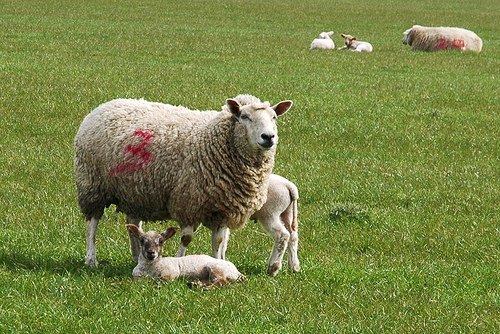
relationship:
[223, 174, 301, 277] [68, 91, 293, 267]
animal next to sheep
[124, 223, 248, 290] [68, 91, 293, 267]
baby next to sheep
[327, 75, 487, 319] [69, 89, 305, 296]
clean grass for sheep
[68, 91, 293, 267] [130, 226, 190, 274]
sheep with baby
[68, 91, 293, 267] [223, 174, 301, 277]
sheep with animal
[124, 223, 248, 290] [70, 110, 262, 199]
baby near sheep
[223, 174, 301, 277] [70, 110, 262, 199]
animal near sheep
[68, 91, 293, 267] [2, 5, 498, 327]
sheep enjoying grass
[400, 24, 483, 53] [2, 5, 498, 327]
ewe enjoying grass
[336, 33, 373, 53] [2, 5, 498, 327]
lambs enjoying grass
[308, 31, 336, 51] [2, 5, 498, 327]
lamb enjoying grass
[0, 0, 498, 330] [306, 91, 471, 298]
green grass on ground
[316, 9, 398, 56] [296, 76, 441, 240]
lambs on grass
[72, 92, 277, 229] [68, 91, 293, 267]
coat on sheep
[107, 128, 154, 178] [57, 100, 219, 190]
letter on wool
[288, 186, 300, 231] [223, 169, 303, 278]
tail on animal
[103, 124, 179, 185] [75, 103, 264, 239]
letter on sheep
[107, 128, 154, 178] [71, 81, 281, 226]
letter on side of sheep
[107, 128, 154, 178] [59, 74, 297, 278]
letter on side of sheep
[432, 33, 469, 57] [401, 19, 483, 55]
letter on side of sheep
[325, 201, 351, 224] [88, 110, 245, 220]
letter on side of sheep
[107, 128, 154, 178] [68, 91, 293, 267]
letter on side of sheep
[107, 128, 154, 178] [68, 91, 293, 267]
letter on sheep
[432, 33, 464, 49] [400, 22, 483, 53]
letter on ewe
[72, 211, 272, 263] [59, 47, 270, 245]
legs of sheep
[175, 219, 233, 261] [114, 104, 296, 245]
legs of sheep